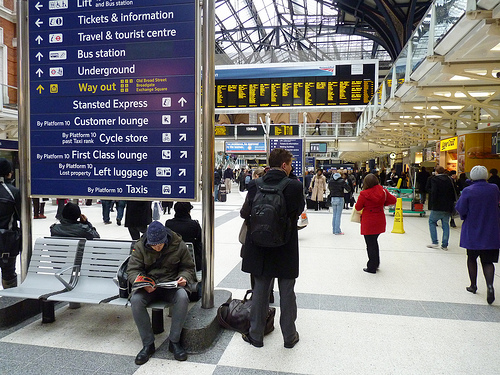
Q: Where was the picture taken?
A: It was taken at the station.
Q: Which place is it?
A: It is a station.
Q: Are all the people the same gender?
A: No, they are both male and female.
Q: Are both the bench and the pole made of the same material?
A: Yes, both the bench and the pole are made of metal.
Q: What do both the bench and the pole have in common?
A: The material, both the bench and the pole are metallic.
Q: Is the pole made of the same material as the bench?
A: Yes, both the pole and the bench are made of metal.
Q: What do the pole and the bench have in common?
A: The material, both the pole and the bench are metallic.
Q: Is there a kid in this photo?
A: No, there are no children.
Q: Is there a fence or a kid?
A: No, there are no children or fences.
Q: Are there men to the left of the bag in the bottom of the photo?
A: Yes, there is a man to the left of the bag.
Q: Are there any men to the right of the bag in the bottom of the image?
A: No, the man is to the left of the bag.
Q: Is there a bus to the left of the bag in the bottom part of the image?
A: No, there is a man to the left of the bag.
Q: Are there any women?
A: Yes, there is a woman.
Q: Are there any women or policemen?
A: Yes, there is a woman.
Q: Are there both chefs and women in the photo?
A: No, there is a woman but no chefs.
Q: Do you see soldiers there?
A: No, there are no soldiers.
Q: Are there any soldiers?
A: No, there are no soldiers.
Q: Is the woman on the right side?
A: Yes, the woman is on the right of the image.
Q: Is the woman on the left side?
A: No, the woman is on the right of the image.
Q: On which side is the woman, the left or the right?
A: The woman is on the right of the image.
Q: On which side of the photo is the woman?
A: The woman is on the right of the image.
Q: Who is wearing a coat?
A: The woman is wearing a coat.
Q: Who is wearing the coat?
A: The woman is wearing a coat.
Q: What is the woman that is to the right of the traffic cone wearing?
A: The woman is wearing a coat.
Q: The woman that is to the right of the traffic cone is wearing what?
A: The woman is wearing a coat.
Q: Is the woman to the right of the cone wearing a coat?
A: Yes, the woman is wearing a coat.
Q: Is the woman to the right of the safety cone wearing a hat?
A: No, the woman is wearing a coat.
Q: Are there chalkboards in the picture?
A: No, there are no chalkboards.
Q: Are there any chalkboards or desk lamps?
A: No, there are no chalkboards or desk lamps.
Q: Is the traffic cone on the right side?
A: Yes, the traffic cone is on the right of the image.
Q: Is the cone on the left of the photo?
A: No, the cone is on the right of the image.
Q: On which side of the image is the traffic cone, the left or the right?
A: The traffic cone is on the right of the image.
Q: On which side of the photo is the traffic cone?
A: The traffic cone is on the right of the image.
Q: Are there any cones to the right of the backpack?
A: Yes, there is a cone to the right of the backpack.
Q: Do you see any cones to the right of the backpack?
A: Yes, there is a cone to the right of the backpack.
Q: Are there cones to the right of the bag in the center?
A: Yes, there is a cone to the right of the backpack.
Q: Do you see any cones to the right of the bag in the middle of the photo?
A: Yes, there is a cone to the right of the backpack.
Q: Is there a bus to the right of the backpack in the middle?
A: No, there is a cone to the right of the backpack.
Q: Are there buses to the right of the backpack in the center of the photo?
A: No, there is a cone to the right of the backpack.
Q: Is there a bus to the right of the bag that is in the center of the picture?
A: No, there is a cone to the right of the backpack.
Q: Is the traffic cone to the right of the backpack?
A: Yes, the traffic cone is to the right of the backpack.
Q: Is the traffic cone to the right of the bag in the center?
A: Yes, the traffic cone is to the right of the backpack.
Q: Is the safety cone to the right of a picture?
A: No, the safety cone is to the right of the backpack.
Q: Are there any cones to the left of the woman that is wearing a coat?
A: Yes, there is a cone to the left of the woman.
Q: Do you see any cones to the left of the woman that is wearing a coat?
A: Yes, there is a cone to the left of the woman.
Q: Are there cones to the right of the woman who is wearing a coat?
A: No, the cone is to the left of the woman.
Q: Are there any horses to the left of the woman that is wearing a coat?
A: No, there is a cone to the left of the woman.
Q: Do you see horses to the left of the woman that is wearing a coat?
A: No, there is a cone to the left of the woman.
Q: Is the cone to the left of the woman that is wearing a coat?
A: Yes, the cone is to the left of the woman.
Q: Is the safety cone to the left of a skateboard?
A: No, the safety cone is to the left of the woman.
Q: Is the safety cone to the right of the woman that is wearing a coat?
A: No, the safety cone is to the left of the woman.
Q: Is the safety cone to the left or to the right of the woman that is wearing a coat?
A: The safety cone is to the left of the woman.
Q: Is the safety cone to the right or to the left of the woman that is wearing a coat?
A: The safety cone is to the left of the woman.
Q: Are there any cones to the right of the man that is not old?
A: Yes, there is a cone to the right of the man.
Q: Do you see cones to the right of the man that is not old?
A: Yes, there is a cone to the right of the man.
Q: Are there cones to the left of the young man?
A: No, the cone is to the right of the man.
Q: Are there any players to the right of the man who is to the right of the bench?
A: No, there is a cone to the right of the man.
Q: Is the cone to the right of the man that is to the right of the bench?
A: Yes, the cone is to the right of the man.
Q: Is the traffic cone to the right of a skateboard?
A: No, the traffic cone is to the right of the man.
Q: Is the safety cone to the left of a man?
A: No, the safety cone is to the right of a man.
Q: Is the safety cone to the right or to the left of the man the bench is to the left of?
A: The safety cone is to the right of the man.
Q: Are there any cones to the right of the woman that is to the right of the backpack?
A: Yes, there is a cone to the right of the woman.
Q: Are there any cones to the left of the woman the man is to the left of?
A: No, the cone is to the right of the woman.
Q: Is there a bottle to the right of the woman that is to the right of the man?
A: No, there is a cone to the right of the woman.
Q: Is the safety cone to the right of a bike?
A: No, the safety cone is to the right of a woman.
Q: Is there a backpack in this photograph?
A: Yes, there is a backpack.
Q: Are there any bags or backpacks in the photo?
A: Yes, there is a backpack.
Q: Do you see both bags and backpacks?
A: Yes, there are both a backpack and a bag.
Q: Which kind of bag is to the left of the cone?
A: The bag is a backpack.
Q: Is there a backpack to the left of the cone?
A: Yes, there is a backpack to the left of the cone.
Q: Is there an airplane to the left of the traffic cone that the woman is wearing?
A: No, there is a backpack to the left of the traffic cone.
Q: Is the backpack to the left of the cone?
A: Yes, the backpack is to the left of the cone.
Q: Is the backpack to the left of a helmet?
A: No, the backpack is to the left of the cone.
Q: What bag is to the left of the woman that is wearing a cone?
A: The bag is a backpack.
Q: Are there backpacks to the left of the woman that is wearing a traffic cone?
A: Yes, there is a backpack to the left of the woman.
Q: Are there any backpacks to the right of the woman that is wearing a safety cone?
A: No, the backpack is to the left of the woman.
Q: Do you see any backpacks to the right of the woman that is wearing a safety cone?
A: No, the backpack is to the left of the woman.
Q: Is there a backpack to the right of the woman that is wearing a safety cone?
A: No, the backpack is to the left of the woman.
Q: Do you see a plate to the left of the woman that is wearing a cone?
A: No, there is a backpack to the left of the woman.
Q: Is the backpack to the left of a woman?
A: Yes, the backpack is to the left of a woman.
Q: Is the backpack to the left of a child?
A: No, the backpack is to the left of a woman.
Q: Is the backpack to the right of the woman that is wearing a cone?
A: No, the backpack is to the left of the woman.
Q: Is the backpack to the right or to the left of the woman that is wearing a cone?
A: The backpack is to the left of the woman.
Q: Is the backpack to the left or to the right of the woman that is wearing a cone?
A: The backpack is to the left of the woman.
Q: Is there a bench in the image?
A: Yes, there is a bench.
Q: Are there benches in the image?
A: Yes, there is a bench.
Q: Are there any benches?
A: Yes, there is a bench.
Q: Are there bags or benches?
A: Yes, there is a bench.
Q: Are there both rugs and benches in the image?
A: No, there is a bench but no rugs.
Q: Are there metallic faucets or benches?
A: Yes, there is a metal bench.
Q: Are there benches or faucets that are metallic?
A: Yes, the bench is metallic.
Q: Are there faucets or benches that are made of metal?
A: Yes, the bench is made of metal.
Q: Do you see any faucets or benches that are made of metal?
A: Yes, the bench is made of metal.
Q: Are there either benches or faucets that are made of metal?
A: Yes, the bench is made of metal.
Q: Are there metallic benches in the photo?
A: Yes, there is a metal bench.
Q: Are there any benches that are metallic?
A: Yes, there is a bench that is metallic.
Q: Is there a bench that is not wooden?
A: Yes, there is a metallic bench.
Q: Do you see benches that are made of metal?
A: Yes, there is a bench that is made of metal.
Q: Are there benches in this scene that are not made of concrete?
A: Yes, there is a bench that is made of metal.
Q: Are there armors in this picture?
A: No, there are no armors.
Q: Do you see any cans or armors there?
A: No, there are no armors or cans.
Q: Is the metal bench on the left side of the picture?
A: Yes, the bench is on the left of the image.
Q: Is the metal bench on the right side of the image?
A: No, the bench is on the left of the image.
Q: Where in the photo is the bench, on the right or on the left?
A: The bench is on the left of the image.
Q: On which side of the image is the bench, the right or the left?
A: The bench is on the left of the image.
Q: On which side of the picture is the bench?
A: The bench is on the left of the image.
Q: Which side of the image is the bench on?
A: The bench is on the left of the image.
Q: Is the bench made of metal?
A: Yes, the bench is made of metal.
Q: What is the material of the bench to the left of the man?
A: The bench is made of metal.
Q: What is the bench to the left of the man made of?
A: The bench is made of metal.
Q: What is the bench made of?
A: The bench is made of metal.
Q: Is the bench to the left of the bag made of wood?
A: No, the bench is made of metal.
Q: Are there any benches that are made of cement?
A: No, there is a bench but it is made of metal.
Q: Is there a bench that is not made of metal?
A: No, there is a bench but it is made of metal.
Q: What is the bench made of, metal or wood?
A: The bench is made of metal.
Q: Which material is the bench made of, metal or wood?
A: The bench is made of metal.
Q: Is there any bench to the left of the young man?
A: Yes, there is a bench to the left of the man.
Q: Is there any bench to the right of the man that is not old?
A: No, the bench is to the left of the man.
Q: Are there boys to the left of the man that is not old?
A: No, there is a bench to the left of the man.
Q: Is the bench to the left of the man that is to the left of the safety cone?
A: Yes, the bench is to the left of the man.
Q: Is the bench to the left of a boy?
A: No, the bench is to the left of the man.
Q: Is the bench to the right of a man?
A: No, the bench is to the left of a man.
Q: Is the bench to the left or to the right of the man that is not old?
A: The bench is to the left of the man.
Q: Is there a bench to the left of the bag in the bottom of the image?
A: Yes, there is a bench to the left of the bag.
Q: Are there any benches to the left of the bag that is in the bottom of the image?
A: Yes, there is a bench to the left of the bag.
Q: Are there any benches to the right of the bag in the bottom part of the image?
A: No, the bench is to the left of the bag.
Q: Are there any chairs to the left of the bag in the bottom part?
A: No, there is a bench to the left of the bag.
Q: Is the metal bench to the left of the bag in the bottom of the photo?
A: Yes, the bench is to the left of the bag.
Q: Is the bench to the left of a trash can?
A: No, the bench is to the left of the bag.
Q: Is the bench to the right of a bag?
A: No, the bench is to the left of a bag.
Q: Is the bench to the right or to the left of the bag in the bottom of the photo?
A: The bench is to the left of the bag.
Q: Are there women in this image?
A: Yes, there is a woman.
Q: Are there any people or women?
A: Yes, there is a woman.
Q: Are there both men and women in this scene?
A: Yes, there are both a woman and a man.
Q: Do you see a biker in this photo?
A: No, there are no bikers.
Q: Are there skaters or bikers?
A: No, there are no bikers or skaters.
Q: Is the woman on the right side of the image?
A: Yes, the woman is on the right of the image.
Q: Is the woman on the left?
A: No, the woman is on the right of the image.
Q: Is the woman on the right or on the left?
A: The woman is on the right of the image.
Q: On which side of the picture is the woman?
A: The woman is on the right of the image.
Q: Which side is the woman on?
A: The woman is on the right of the image.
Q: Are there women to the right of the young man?
A: Yes, there is a woman to the right of the man.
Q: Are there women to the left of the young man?
A: No, the woman is to the right of the man.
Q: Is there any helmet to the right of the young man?
A: No, there is a woman to the right of the man.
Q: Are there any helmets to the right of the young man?
A: No, there is a woman to the right of the man.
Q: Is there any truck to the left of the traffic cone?
A: No, there is a woman to the left of the traffic cone.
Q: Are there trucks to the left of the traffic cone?
A: No, there is a woman to the left of the traffic cone.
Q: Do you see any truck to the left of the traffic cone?
A: No, there is a woman to the left of the traffic cone.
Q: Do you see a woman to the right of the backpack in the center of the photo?
A: Yes, there is a woman to the right of the backpack.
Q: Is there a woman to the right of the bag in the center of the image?
A: Yes, there is a woman to the right of the backpack.